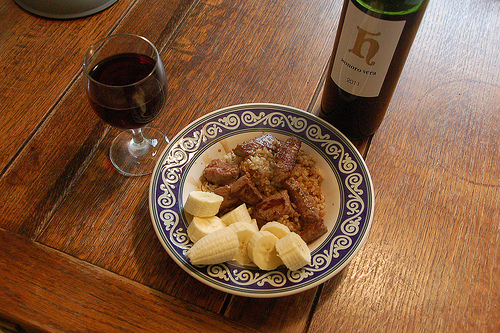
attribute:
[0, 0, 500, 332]
table — wooden, wood grain, brown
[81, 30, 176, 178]
glass — half full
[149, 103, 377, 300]
bowl — blue, round, white, patterned, decorated, designed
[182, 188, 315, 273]
banana — cut into pieces, white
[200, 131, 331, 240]
rice and meat — mixed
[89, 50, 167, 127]
wine — red, dark, purple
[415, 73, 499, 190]
ring — a stain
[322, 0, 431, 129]
bottle — green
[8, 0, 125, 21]
pot — silver, black, round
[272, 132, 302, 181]
meat — brown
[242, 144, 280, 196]
rice — brown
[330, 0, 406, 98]
label — white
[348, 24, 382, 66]
h — gold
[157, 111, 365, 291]
design — white, curvy